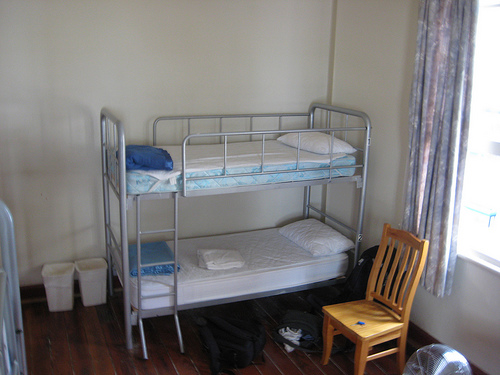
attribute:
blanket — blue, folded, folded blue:
[115, 144, 175, 170]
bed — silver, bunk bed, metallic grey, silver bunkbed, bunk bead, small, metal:
[100, 101, 373, 359]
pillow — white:
[276, 130, 357, 156]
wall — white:
[1, 0, 338, 288]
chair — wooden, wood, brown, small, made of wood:
[320, 221, 430, 374]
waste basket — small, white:
[73, 257, 108, 307]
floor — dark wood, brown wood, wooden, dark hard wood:
[22, 283, 439, 374]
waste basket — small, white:
[42, 262, 76, 313]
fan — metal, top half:
[401, 341, 473, 374]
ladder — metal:
[135, 190, 184, 360]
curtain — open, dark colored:
[399, 2, 479, 299]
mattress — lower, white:
[111, 226, 349, 309]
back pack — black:
[192, 313, 266, 374]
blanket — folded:
[128, 239, 181, 275]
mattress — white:
[106, 139, 356, 194]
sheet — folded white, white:
[196, 248, 245, 270]